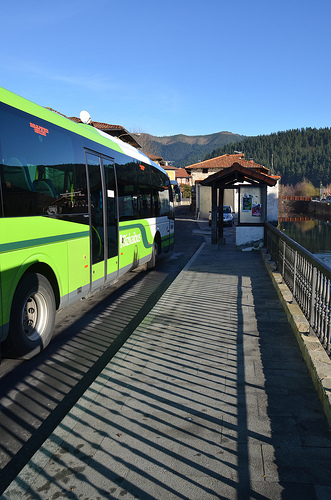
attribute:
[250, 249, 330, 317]
rails — iron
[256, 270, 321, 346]
base — stone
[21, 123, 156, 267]
bus — green, light reen, parked, long, lime green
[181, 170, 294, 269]
stop — sheltered, covered, pavillion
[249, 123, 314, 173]
trees — lush, tall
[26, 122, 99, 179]
lights — orange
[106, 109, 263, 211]
mountains — distant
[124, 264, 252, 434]
sidewalk — alongside, cement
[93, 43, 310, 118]
sky — blue, clear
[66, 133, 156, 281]
door — double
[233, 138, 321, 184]
hill — covered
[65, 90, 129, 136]
dish — satellite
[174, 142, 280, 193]
roof — brick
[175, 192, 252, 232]
car — parked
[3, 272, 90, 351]
tire — rubber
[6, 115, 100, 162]
letters — orange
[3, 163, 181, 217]
glass — tinted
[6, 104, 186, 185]
sign — lighted